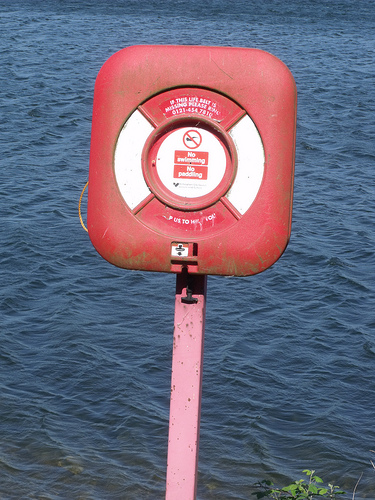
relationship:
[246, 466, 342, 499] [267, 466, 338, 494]
bush of a bush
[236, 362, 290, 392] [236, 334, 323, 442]
ripples in water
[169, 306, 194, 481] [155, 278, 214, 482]
paint on a post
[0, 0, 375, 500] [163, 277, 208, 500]
water behind arm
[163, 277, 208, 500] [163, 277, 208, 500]
paint on arm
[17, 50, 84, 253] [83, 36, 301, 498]
water behind device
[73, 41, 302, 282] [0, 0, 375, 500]
life preserver in water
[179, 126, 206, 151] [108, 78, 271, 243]
device has warning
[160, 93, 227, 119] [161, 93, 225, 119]
lettering on device